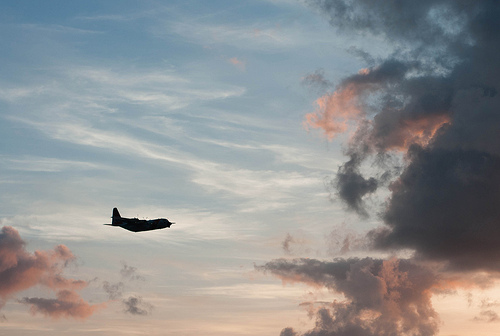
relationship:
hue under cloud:
[431, 281, 483, 332] [0, 0, 500, 336]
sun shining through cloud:
[306, 111, 347, 134] [0, 0, 500, 336]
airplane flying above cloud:
[103, 207, 176, 234] [0, 0, 500, 336]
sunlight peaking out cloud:
[231, 281, 268, 332] [0, 0, 500, 336]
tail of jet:
[112, 207, 121, 225] [108, 193, 178, 234]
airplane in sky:
[103, 204, 176, 234] [3, 1, 495, 332]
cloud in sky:
[0, 0, 500, 336] [3, 1, 495, 332]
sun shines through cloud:
[308, 80, 455, 148] [0, 0, 500, 336]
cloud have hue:
[0, 0, 500, 336] [303, 83, 370, 139]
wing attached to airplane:
[169, 220, 175, 225] [103, 204, 176, 234]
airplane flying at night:
[103, 207, 176, 234] [12, 9, 473, 324]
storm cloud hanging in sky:
[332, 7, 483, 285] [3, 1, 495, 332]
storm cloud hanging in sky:
[252, 256, 444, 334] [3, 1, 495, 332]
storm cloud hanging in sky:
[301, 58, 422, 143] [3, 1, 495, 332]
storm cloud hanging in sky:
[304, 1, 448, 47] [3, 1, 495, 332]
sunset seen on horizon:
[2, 280, 484, 330] [1, 309, 483, 334]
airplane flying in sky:
[103, 207, 176, 234] [3, 1, 495, 332]